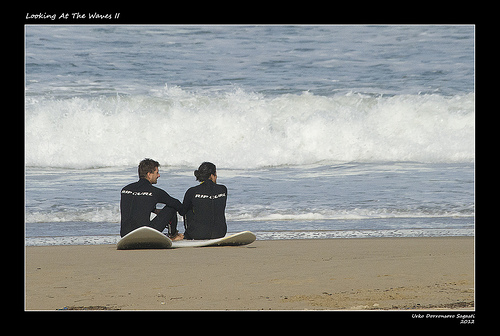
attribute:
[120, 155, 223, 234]
people — sitting, couple, surfers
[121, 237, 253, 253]
surfboards — white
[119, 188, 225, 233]
wetsuits — black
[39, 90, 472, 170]
wave — choppy, rolling, large, white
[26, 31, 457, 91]
water — calm, white, breaking, blue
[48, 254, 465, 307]
beach — hard, sandy, brown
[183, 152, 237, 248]
woman — pictured, surfer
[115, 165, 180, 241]
man — sitting, barefoot, surfer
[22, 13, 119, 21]
title — pictured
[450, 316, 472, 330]
year — pictured, stamped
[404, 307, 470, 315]
photographer — stamped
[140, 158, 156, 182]
hair — brown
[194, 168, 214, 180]
hair — ponytail, brown